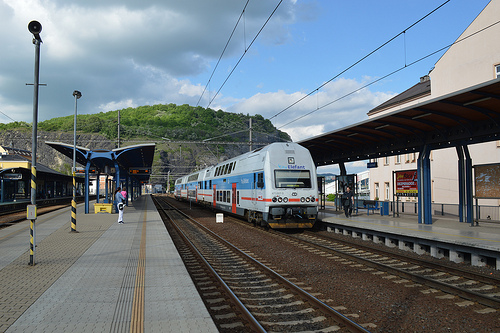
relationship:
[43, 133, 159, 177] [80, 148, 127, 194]
roofs on supports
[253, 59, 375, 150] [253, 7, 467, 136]
clouds under sky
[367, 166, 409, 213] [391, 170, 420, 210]
window behind sign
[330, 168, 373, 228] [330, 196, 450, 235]
person walking on platform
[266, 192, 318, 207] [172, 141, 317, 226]
headlights of train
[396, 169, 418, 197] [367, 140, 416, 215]
advertisement on wall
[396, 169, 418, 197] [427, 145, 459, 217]
advertisement on wall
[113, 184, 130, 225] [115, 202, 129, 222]
woman wearing pants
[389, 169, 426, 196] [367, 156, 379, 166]
sign hanging from chain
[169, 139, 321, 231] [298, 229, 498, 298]
train on train track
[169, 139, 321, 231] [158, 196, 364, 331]
train on train track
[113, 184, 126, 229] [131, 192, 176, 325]
person standing on platform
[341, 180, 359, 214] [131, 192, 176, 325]
person standing on platform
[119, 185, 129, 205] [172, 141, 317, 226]
person waiting on train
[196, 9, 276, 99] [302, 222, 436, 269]
wire line above tracks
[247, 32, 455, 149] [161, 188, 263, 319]
wire line above tracks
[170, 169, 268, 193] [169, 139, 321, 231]
stripe down side of train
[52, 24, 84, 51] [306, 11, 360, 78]
clouds in sky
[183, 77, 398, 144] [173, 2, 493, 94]
white clouds in blue sky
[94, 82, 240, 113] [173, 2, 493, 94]
white clouds in blue sky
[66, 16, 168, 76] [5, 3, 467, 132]
white clouds in sky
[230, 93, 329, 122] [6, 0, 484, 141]
cloud in sky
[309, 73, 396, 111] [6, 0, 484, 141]
cloud in sky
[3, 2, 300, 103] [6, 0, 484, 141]
cloud in sky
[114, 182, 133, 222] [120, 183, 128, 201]
mother carrying baby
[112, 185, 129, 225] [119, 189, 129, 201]
mother carrying baby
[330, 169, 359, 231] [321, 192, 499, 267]
man at platform